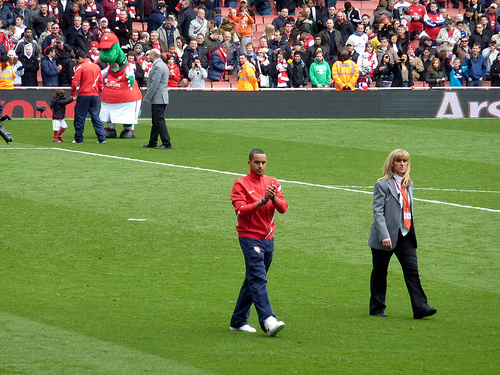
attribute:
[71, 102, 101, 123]
pants — blue, black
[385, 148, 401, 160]
hair — blonde, dark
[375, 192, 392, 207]
blazer — gray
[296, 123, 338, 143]
field — green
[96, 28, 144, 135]
mascot — green, standing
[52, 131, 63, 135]
socks — red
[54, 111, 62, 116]
hoodie — blue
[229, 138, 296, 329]
man — bald, walking, standing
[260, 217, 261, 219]
shirt — red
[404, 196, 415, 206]
tie — red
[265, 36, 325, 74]
people — walking, standing, watching, audience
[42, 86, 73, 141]
child — little, walking, small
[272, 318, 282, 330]
shoes — white, pair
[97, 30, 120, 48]
cap — red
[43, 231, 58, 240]
grass — green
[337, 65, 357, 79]
jacket — yellow